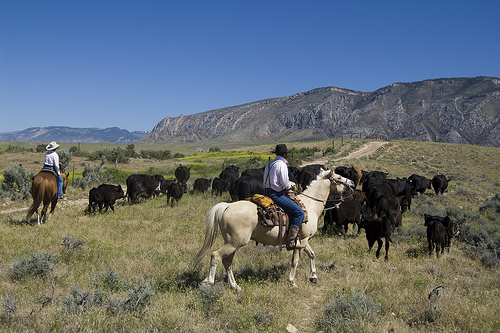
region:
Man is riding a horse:
[176, 117, 368, 309]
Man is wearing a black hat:
[236, 133, 311, 183]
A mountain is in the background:
[144, 65, 496, 150]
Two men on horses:
[22, 134, 472, 294]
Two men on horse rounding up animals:
[11, 131, 461, 288]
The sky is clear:
[14, 9, 457, 127]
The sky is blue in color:
[6, 5, 481, 102]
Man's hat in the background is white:
[33, 136, 76, 167]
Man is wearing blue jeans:
[259, 172, 319, 252]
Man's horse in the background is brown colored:
[12, 140, 89, 235]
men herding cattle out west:
[14, 98, 428, 298]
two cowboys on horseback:
[25, 119, 395, 273]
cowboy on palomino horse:
[186, 123, 457, 290]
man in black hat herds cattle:
[177, 121, 440, 269]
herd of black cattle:
[82, 136, 418, 222]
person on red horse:
[18, 129, 105, 254]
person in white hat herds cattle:
[14, 124, 150, 231]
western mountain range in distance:
[53, 89, 463, 159]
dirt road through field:
[275, 138, 404, 162]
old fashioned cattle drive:
[18, 88, 390, 287]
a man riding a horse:
[189, 128, 358, 298]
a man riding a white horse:
[184, 116, 376, 302]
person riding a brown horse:
[21, 131, 78, 233]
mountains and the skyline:
[131, 72, 421, 145]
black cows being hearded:
[83, 150, 218, 217]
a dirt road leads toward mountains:
[287, 113, 419, 170]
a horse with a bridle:
[303, 157, 358, 220]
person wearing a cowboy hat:
[23, 130, 82, 228]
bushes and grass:
[20, 236, 152, 332]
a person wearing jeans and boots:
[251, 132, 331, 278]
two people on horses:
[17, 129, 357, 292]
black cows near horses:
[18, 135, 459, 261]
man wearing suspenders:
[255, 140, 296, 200]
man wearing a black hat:
[265, 136, 293, 161]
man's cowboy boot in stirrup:
[280, 221, 306, 254]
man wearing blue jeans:
[268, 185, 304, 230]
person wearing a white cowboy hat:
[35, 135, 61, 160]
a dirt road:
[295, 135, 395, 175]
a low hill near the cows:
[85, 70, 495, 280]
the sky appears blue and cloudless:
[1, 3, 490, 118]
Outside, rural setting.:
[2, 5, 489, 331]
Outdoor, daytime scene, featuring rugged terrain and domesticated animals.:
[3, 6, 498, 320]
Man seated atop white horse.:
[199, 145, 368, 310]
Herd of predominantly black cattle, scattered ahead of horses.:
[88, 125, 491, 267]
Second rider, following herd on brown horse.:
[27, 137, 77, 242]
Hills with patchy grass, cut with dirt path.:
[10, 133, 498, 310]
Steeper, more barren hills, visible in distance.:
[28, 83, 498, 138]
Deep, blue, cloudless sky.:
[52, 27, 334, 81]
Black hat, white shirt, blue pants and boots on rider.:
[256, 142, 307, 271]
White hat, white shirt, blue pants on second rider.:
[27, 134, 72, 216]